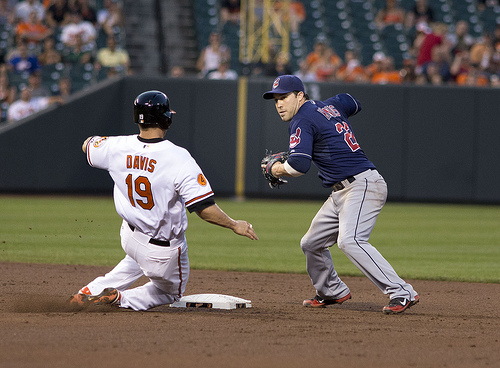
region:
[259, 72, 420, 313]
Cleveland Indians baseball player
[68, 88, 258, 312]
Baltimore Orioles player sliding into base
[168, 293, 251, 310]
second base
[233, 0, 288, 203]
left field foul pole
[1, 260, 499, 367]
dirt in infield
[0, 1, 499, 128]
spectators in the stands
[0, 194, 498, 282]
grass in outfield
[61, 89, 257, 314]
baseball player sliding into second base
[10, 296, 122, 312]
dirt from sliding player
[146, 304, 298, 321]
shadow of basebal player on infield dirt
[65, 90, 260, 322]
a baseball player playing baseball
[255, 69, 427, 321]
a baseball player playing baseball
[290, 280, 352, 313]
the shoe of a baseball player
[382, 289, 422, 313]
the shoe of a baseball player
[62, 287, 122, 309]
the shoe of a baseball player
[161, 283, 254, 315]
a white baseball base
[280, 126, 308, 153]
a cleveland indians logo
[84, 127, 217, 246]
a white baseball jersey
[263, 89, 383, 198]
a blue baseball jersey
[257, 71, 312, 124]
the head of a man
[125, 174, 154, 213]
Red numbers on shirt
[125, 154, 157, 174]
Red letters on shirt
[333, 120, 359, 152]
Red numbers on shirt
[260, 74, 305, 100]
Blue and red baseball cap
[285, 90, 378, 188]
Blue and red and white shirt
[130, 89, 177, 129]
Black helmet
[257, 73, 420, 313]
Man wearing blue and red baseball cap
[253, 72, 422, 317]
Man wearing blue and red and white shirt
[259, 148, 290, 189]
Black and red baseball glove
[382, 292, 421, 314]
Red and black and white shoes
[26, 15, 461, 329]
an action scene at a baseball game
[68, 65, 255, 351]
a baseball player sliding for the base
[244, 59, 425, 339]
this player is playing defense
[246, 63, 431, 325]
he plays for the Indians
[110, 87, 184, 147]
he has on a batter's helmet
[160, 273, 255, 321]
the base is white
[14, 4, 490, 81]
the spectators in the background are blurry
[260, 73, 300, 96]
blue hat on player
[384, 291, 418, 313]
orange and black shoe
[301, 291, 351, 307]
orange and black shoe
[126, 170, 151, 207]
orange number on jersey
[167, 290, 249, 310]
white base in dirt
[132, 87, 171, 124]
black helmet on player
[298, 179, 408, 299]
grey pants of player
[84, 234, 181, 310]
white pants of player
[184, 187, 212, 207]
orange stripe on sleeve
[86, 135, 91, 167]
orange stripe on sleeve